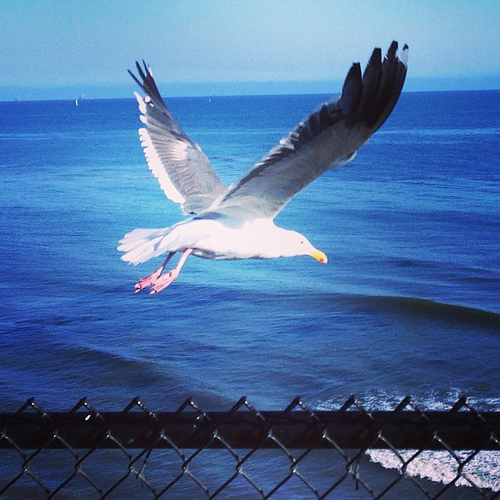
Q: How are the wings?
A: Fully extended?.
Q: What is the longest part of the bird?
A: It's wing span.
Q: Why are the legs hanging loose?
A: The creature is in flight.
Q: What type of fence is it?
A: Chain link.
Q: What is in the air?
A: Bird.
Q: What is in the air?
A: Bird.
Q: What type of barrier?
A: Fence.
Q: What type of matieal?
A: Metal.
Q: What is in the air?
A: Bird.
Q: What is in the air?
A: Bird.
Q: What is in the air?
A: Bird.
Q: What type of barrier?
A: Fence.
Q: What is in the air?
A: Bird.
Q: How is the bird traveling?
A: Flying in air.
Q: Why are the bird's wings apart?
A: It's flying.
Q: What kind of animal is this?
A: Bird.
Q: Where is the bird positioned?
A: Above a fence.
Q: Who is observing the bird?
A: The wildlife photographer.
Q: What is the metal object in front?
A: Fence.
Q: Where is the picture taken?
A: Ocean.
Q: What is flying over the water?
A: Seagull.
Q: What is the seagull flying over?
A: Water.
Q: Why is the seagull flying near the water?
A: For fish.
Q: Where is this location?
A: Ocean.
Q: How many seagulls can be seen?
A: One.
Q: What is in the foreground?
A: Fence.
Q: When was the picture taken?
A: Daytime.